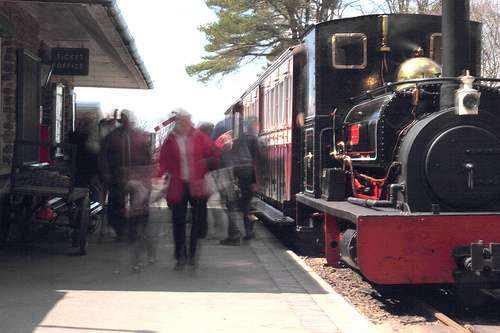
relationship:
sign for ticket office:
[52, 47, 89, 78] [0, 0, 73, 244]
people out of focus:
[103, 108, 254, 266] [71, 95, 266, 266]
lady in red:
[160, 111, 234, 275] [221, 0, 499, 290]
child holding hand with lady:
[122, 173, 158, 272] [160, 111, 234, 275]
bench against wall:
[6, 168, 107, 253] [1, 6, 73, 236]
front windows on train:
[331, 35, 442, 64] [221, 0, 499, 290]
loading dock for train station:
[230, 185, 292, 227] [0, 0, 379, 329]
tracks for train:
[397, 280, 496, 331] [221, 0, 499, 290]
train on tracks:
[221, 0, 499, 290] [397, 280, 496, 331]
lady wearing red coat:
[160, 111, 234, 275] [160, 134, 222, 202]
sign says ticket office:
[52, 47, 89, 78] [56, 51, 85, 72]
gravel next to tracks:
[308, 250, 441, 332] [397, 280, 496, 331]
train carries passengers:
[221, 0, 499, 290] [297, 55, 315, 135]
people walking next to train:
[103, 108, 254, 266] [221, 0, 499, 290]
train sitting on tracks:
[221, 0, 499, 290] [397, 280, 496, 331]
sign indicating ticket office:
[52, 47, 89, 78] [0, 0, 73, 244]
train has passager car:
[221, 0, 499, 290] [240, 42, 302, 245]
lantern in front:
[453, 71, 480, 115] [386, 1, 499, 282]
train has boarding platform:
[221, 0, 499, 290] [248, 198, 292, 227]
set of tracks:
[407, 287, 499, 331] [397, 280, 496, 331]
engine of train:
[296, 0, 498, 285] [221, 0, 499, 290]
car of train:
[240, 42, 302, 245] [221, 0, 499, 290]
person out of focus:
[101, 112, 149, 260] [71, 95, 266, 266]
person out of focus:
[160, 111, 234, 275] [71, 95, 266, 266]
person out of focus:
[214, 112, 259, 245] [71, 95, 266, 266]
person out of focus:
[122, 173, 158, 272] [71, 95, 266, 266]